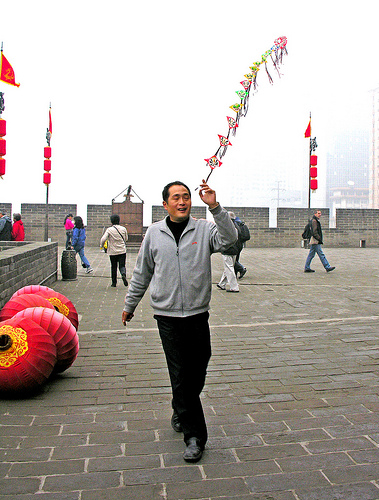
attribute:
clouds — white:
[3, 2, 376, 201]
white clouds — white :
[99, 41, 190, 110]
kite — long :
[197, 35, 288, 194]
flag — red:
[298, 104, 323, 148]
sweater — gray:
[123, 202, 239, 319]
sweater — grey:
[102, 211, 245, 352]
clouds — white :
[106, 94, 168, 140]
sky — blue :
[107, 43, 159, 136]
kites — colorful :
[203, 34, 288, 181]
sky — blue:
[1, 1, 376, 226]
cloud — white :
[0, 0, 377, 230]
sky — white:
[94, 103, 190, 172]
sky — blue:
[83, 41, 178, 117]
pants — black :
[151, 314, 214, 439]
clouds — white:
[128, 75, 246, 162]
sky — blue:
[179, 56, 286, 124]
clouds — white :
[95, 23, 211, 105]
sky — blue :
[3, 6, 370, 193]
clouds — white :
[312, 75, 358, 100]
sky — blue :
[83, 19, 186, 154]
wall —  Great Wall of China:
[251, 211, 286, 259]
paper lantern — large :
[0, 312, 55, 390]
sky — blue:
[304, 47, 334, 88]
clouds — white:
[47, 21, 228, 117]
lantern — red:
[1, 307, 76, 404]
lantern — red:
[3, 284, 78, 334]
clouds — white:
[0, 4, 321, 106]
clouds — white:
[2, 0, 315, 151]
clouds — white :
[32, 89, 374, 171]